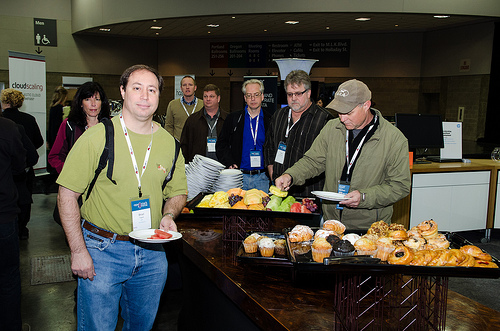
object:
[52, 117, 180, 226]
backpack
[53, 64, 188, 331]
man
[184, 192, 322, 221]
tray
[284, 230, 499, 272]
tray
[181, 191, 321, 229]
container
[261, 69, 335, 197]
man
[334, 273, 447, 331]
crate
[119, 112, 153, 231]
badge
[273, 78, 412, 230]
man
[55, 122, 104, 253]
arm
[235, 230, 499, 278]
plate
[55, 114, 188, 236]
shirt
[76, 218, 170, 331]
jeans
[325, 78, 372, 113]
cap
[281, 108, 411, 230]
coat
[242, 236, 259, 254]
pastries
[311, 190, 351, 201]
plate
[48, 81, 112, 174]
lady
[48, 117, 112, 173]
shirt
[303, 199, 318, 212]
fruit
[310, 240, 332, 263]
muffin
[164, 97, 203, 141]
sweater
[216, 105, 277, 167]
jacket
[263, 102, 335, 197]
shirt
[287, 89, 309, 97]
glasses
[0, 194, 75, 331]
ground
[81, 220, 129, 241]
belt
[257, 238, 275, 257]
pastry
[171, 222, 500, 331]
table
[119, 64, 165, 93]
hair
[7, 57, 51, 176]
banner